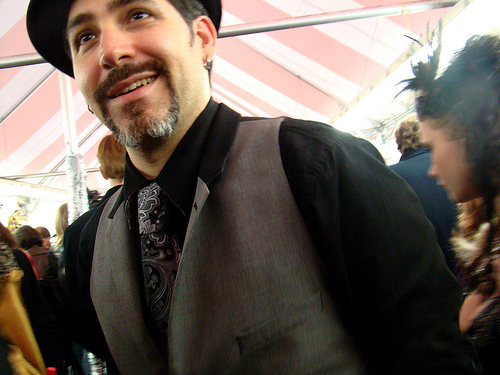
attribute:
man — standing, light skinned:
[26, 0, 461, 369]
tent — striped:
[4, 0, 437, 196]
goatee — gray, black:
[94, 64, 181, 146]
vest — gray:
[78, 116, 356, 373]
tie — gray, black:
[126, 182, 186, 334]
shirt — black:
[73, 125, 463, 373]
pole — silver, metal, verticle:
[3, 0, 444, 72]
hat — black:
[28, 0, 234, 72]